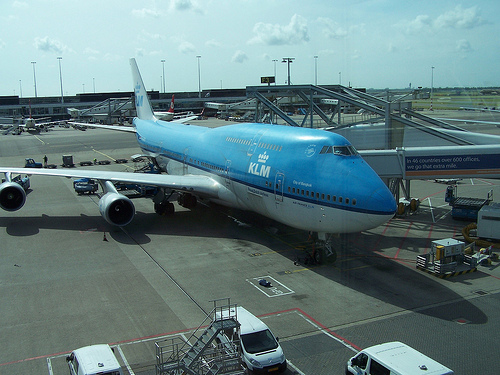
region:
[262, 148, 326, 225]
airplane is baby blue and white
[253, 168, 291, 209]
dark blue stripe in the middle of plane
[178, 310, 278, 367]
portable staircase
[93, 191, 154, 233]
engine on the plane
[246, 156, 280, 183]
KLM is written in white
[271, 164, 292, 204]
door on the plane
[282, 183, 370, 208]
passenger windows on the plane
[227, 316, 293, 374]
white van next to the staircase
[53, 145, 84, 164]
passenger luggage carrier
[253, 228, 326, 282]
yellow lines on the tarmac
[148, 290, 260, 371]
metal movable stair platform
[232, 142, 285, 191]
logo for KLM on the side of the plane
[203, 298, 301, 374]
white van in a parking spot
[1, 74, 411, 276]
big blue jet airplane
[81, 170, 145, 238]
jet engine under the wing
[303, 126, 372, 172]
airplane's cockpit windows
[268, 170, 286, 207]
door on the side of the airplane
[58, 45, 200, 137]
tail section of the airplane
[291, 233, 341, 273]
front landing gear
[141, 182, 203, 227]
rear landing gear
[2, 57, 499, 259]
large blue plane from the Netherlands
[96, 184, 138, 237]
an under wing engine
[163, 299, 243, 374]
portable stairs to reach entry door to plane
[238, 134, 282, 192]
Logo of the airlines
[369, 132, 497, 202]
a jetbridge attached to plane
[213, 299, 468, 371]
two white vans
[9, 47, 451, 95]
tall overhead lights in distance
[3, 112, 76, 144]
plane parked in rear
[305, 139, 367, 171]
window in the cockpit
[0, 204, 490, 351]
shadow of plane on pavement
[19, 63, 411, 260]
white and blue airplane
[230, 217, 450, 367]
red lines painted on tarmac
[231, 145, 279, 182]
white lettering on blue background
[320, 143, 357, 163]
front windows of plane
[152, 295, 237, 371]
black staircase next to white van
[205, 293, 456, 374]
two white vans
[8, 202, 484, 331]
airplane's shadow on tarmac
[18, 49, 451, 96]
light poles in background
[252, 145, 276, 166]
white crowd painted on side of plane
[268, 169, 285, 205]
door on side of blue and white plane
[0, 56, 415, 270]
plane on the tarmac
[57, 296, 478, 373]
three white vans on the tarmac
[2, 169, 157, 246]
two jet engines under the wing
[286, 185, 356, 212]
row of windows on the side of the plane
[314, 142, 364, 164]
windows of the cockpit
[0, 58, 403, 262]
blue and white airplane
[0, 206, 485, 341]
shadow from the plane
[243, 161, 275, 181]
white writing on the side of the plane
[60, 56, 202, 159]
tail of the plane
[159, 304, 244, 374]
movable set of stairs